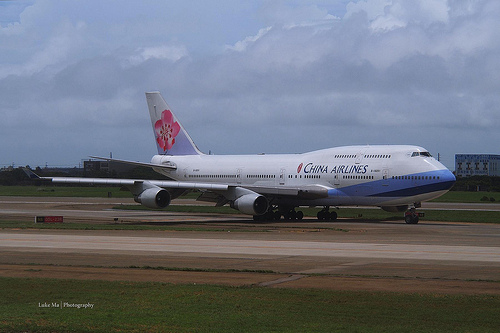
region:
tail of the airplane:
[130, 88, 204, 152]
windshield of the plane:
[405, 145, 436, 157]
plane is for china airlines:
[292, 158, 370, 178]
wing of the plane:
[164, 178, 334, 199]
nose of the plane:
[418, 168, 449, 189]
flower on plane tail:
[143, 116, 181, 152]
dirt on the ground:
[135, 230, 228, 265]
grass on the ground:
[199, 310, 329, 328]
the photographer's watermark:
[30, 292, 105, 317]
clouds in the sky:
[223, 110, 309, 127]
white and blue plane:
[97, 95, 404, 208]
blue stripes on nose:
[412, 163, 462, 195]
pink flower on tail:
[143, 102, 193, 157]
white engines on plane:
[120, 170, 312, 225]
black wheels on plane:
[302, 200, 436, 244]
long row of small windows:
[212, 152, 372, 192]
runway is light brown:
[168, 234, 360, 266]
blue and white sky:
[235, 11, 379, 139]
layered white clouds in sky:
[179, 0, 375, 134]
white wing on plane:
[38, 162, 309, 212]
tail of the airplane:
[140, 92, 193, 153]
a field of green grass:
[133, 290, 286, 330]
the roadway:
[390, 224, 460, 269]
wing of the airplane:
[31, 168, 81, 190]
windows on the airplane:
[399, 172, 427, 184]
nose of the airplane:
[437, 166, 459, 186]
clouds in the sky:
[270, 40, 417, 94]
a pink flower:
[147, 111, 186, 155]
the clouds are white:
[29, 33, 123, 106]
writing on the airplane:
[303, 160, 368, 175]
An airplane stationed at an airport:
[28, 86, 460, 236]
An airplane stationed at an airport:
[20, 86, 465, 232]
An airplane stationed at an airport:
[27, 87, 464, 237]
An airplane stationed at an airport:
[25, 88, 471, 230]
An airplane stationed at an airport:
[22, 85, 477, 231]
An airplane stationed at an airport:
[22, 86, 469, 241]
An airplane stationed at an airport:
[30, 88, 472, 235]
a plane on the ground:
[85, 101, 472, 283]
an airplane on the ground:
[71, 34, 428, 287]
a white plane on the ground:
[80, 27, 467, 330]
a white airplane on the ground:
[153, 58, 488, 320]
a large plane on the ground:
[198, 68, 493, 294]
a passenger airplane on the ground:
[179, 80, 490, 257]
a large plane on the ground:
[204, 104, 386, 248]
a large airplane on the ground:
[197, 103, 493, 290]